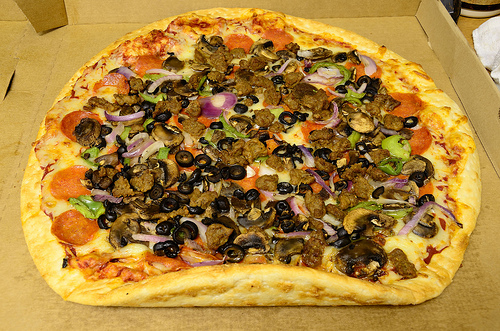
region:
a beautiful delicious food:
[49, 20, 460, 315]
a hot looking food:
[13, 25, 477, 305]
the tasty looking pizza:
[38, 13, 480, 292]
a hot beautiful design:
[100, 58, 420, 265]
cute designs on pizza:
[92, 48, 422, 261]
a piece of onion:
[193, 78, 248, 117]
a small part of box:
[20, 0, 98, 43]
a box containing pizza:
[5, 1, 496, 321]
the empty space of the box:
[366, 8, 452, 53]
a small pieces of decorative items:
[180, 149, 215, 184]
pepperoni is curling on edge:
[48, 206, 99, 249]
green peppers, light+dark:
[371, 132, 416, 182]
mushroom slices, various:
[332, 207, 398, 282]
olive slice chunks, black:
[268, 113, 425, 208]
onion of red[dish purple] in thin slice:
[97, 50, 381, 160]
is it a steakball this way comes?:
[304, 127, 352, 177]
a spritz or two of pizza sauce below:
[37, 3, 491, 285]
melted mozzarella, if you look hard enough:
[165, 28, 437, 282]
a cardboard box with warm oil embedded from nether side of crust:
[3, 0, 497, 330]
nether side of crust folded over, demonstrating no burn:
[68, 256, 426, 320]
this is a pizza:
[101, 44, 367, 257]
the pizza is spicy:
[144, 57, 373, 238]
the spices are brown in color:
[226, 137, 253, 156]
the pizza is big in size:
[425, 117, 471, 188]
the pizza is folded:
[198, 267, 325, 299]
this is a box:
[383, 5, 434, 40]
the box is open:
[380, 6, 427, 36]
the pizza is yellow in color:
[447, 130, 472, 172]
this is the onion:
[211, 95, 233, 109]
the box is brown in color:
[382, 17, 424, 42]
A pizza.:
[30, 6, 485, 326]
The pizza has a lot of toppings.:
[25, 4, 487, 314]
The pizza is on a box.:
[0, 1, 497, 329]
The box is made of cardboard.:
[0, 1, 497, 329]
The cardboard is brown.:
[1, 1, 498, 329]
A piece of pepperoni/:
[42, 209, 104, 254]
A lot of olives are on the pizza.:
[130, 217, 201, 259]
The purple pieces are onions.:
[390, 192, 460, 244]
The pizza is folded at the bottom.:
[30, 245, 477, 327]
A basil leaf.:
[65, 187, 117, 222]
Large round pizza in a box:
[33, 8, 498, 300]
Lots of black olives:
[100, 140, 376, 269]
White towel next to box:
[466, 19, 498, 82]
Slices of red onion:
[91, 63, 418, 210]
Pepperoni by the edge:
[47, 93, 105, 265]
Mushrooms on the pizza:
[113, 183, 393, 250]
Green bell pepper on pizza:
[218, 58, 433, 260]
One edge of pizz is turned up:
[93, 258, 430, 330]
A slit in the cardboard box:
[5, 57, 25, 114]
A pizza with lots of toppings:
[41, 31, 456, 306]